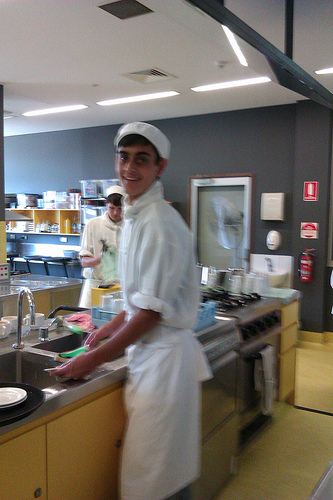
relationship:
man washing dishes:
[50, 119, 207, 492] [41, 365, 75, 373]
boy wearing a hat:
[49, 118, 206, 492] [113, 120, 172, 159]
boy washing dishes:
[49, 118, 206, 492] [42, 359, 81, 374]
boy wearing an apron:
[49, 118, 206, 492] [115, 328, 213, 488]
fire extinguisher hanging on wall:
[294, 245, 316, 285] [293, 105, 322, 410]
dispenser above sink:
[263, 228, 284, 251] [248, 251, 291, 283]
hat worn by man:
[113, 120, 172, 159] [50, 118, 214, 498]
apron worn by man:
[115, 328, 213, 488] [50, 118, 214, 498]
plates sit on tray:
[4, 383, 27, 410] [3, 381, 45, 423]